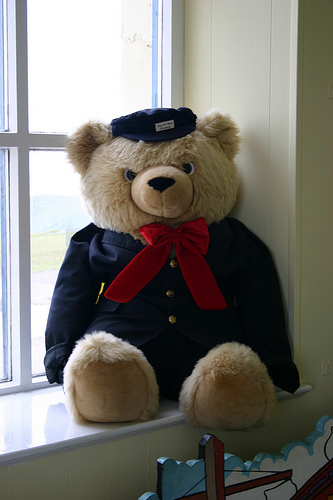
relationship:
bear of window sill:
[43, 105, 300, 430] [0, 383, 312, 465]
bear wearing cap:
[43, 105, 300, 430] [109, 105, 200, 142]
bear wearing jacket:
[43, 105, 300, 430] [43, 214, 297, 383]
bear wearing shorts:
[43, 105, 278, 423] [92, 319, 229, 370]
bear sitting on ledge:
[43, 105, 300, 430] [3, 347, 316, 457]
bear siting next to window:
[43, 105, 300, 430] [1, 10, 171, 390]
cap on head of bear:
[109, 104, 197, 143] [29, 96, 312, 442]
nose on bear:
[142, 168, 188, 197] [43, 105, 300, 430]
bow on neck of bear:
[105, 217, 228, 309] [43, 105, 300, 430]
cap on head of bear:
[109, 105, 200, 142] [50, 99, 176, 437]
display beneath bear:
[144, 412, 331, 497] [43, 105, 300, 430]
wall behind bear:
[176, 9, 310, 380] [43, 105, 300, 430]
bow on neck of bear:
[134, 221, 210, 259] [29, 96, 312, 442]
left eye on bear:
[178, 161, 197, 178] [43, 105, 300, 430]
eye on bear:
[90, 155, 176, 193] [37, 118, 245, 356]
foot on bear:
[52, 332, 174, 432] [50, 97, 297, 419]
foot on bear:
[178, 340, 276, 431] [43, 105, 300, 430]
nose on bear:
[141, 173, 180, 199] [58, 76, 299, 376]